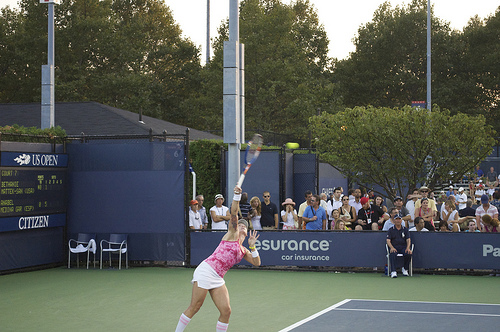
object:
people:
[264, 193, 280, 226]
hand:
[232, 183, 242, 196]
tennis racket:
[235, 132, 265, 189]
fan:
[298, 195, 328, 234]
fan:
[277, 195, 301, 234]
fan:
[206, 188, 228, 229]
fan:
[181, 198, 203, 234]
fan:
[471, 195, 494, 225]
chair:
[99, 230, 129, 275]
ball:
[282, 140, 297, 150]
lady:
[175, 184, 264, 331]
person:
[386, 219, 415, 279]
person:
[304, 198, 327, 236]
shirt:
[299, 207, 329, 234]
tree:
[309, 106, 489, 199]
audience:
[250, 178, 500, 231]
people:
[340, 194, 358, 225]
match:
[12, 131, 470, 324]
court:
[276, 287, 497, 327]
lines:
[333, 303, 499, 317]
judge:
[385, 216, 415, 265]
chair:
[379, 243, 422, 275]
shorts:
[190, 255, 228, 291]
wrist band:
[249, 248, 261, 260]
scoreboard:
[0, 145, 62, 232]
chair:
[66, 230, 98, 270]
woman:
[277, 198, 303, 230]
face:
[284, 200, 293, 210]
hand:
[285, 203, 289, 210]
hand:
[288, 204, 294, 210]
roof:
[2, 100, 225, 142]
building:
[2, 101, 226, 142]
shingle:
[124, 122, 134, 130]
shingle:
[88, 121, 99, 125]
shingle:
[101, 108, 111, 113]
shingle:
[57, 119, 67, 124]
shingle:
[21, 108, 31, 113]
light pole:
[220, 0, 247, 214]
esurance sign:
[248, 239, 329, 250]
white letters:
[250, 236, 499, 256]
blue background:
[190, 231, 499, 269]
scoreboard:
[0, 164, 68, 214]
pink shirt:
[207, 237, 242, 278]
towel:
[72, 243, 85, 253]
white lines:
[274, 295, 356, 328]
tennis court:
[1, 262, 498, 329]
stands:
[427, 172, 497, 233]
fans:
[354, 197, 391, 229]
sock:
[175, 310, 193, 330]